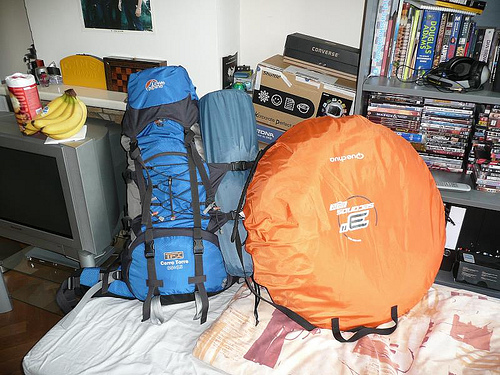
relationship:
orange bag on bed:
[252, 99, 457, 341] [101, 284, 288, 373]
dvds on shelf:
[406, 86, 490, 183] [442, 191, 499, 214]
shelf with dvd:
[366, 71, 427, 111] [370, 95, 420, 115]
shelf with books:
[366, 71, 427, 111] [377, 4, 427, 75]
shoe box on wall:
[282, 29, 363, 76] [2, 1, 362, 128]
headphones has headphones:
[391, 55, 494, 96] [391, 55, 494, 95]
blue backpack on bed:
[100, 72, 237, 312] [25, 217, 490, 374]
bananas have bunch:
[15, 87, 88, 140] [21, 85, 88, 138]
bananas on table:
[19, 87, 91, 136] [0, 238, 134, 319]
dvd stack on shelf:
[422, 97, 470, 184] [431, 171, 498, 210]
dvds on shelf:
[353, 5, 498, 215] [354, 7, 480, 300]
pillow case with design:
[198, 249, 495, 373] [244, 278, 499, 373]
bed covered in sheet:
[61, 279, 481, 374] [58, 299, 222, 373]